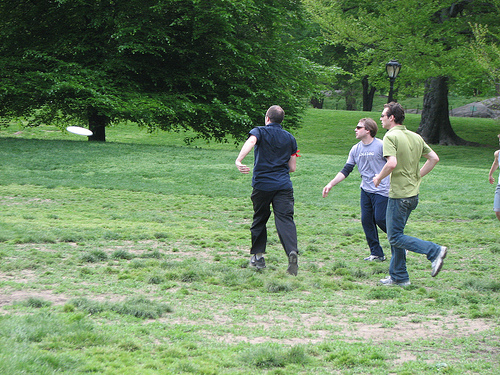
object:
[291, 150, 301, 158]
ribbon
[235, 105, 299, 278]
man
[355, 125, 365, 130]
sunglasses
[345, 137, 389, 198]
shirt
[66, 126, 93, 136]
frisbee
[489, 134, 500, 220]
man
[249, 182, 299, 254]
pants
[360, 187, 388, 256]
pants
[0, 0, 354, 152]
leaves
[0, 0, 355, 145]
tree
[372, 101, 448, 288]
man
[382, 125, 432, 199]
green shirt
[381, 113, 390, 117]
sunglasses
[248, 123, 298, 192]
shirt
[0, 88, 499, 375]
ground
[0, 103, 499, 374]
field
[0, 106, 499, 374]
grass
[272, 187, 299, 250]
leg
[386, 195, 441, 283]
denim pants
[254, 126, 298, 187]
back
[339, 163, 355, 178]
elbow pad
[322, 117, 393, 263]
man